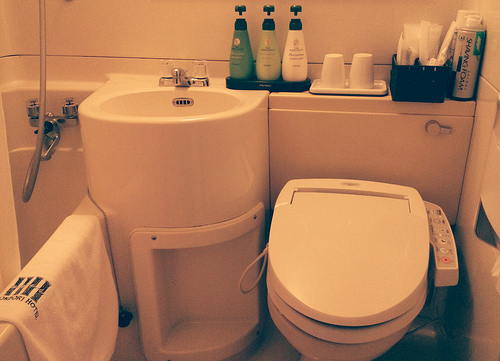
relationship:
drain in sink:
[172, 95, 194, 108] [73, 69, 269, 229]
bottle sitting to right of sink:
[228, 2, 254, 83] [73, 69, 269, 229]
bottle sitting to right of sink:
[253, 1, 283, 82] [73, 69, 269, 229]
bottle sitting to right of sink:
[279, 1, 310, 82] [73, 69, 269, 229]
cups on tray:
[317, 48, 383, 95] [305, 73, 386, 100]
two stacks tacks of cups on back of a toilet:
[299, 50, 389, 100] [202, 183, 448, 332]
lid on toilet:
[270, 178, 434, 307] [264, 87, 474, 331]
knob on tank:
[422, 120, 454, 141] [270, 82, 463, 199]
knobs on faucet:
[157, 57, 207, 77] [160, 68, 206, 85]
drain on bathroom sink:
[168, 95, 195, 108] [77, 71, 269, 358]